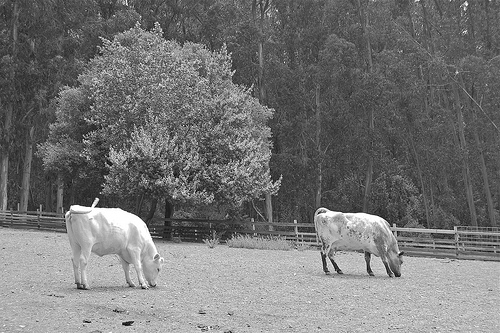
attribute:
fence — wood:
[404, 221, 484, 253]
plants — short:
[224, 230, 295, 252]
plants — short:
[292, 233, 314, 250]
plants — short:
[201, 237, 226, 248]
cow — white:
[54, 189, 182, 294]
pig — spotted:
[313, 203, 405, 280]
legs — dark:
[318, 247, 393, 276]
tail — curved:
[312, 205, 329, 239]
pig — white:
[53, 195, 166, 296]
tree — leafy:
[30, 14, 310, 213]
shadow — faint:
[73, 278, 147, 294]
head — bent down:
[134, 243, 170, 303]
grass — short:
[227, 226, 301, 252]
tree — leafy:
[33, 16, 284, 242]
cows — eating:
[50, 139, 427, 311]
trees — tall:
[7, 7, 484, 228]